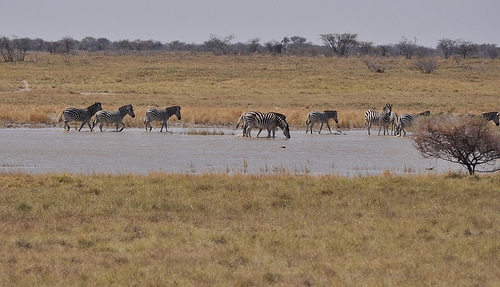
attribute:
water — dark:
[103, 137, 259, 169]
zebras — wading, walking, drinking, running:
[53, 93, 499, 141]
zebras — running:
[50, 97, 183, 134]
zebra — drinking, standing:
[238, 111, 292, 141]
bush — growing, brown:
[418, 116, 498, 182]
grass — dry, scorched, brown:
[158, 66, 223, 80]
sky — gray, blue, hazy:
[223, 3, 287, 27]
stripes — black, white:
[255, 118, 272, 126]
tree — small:
[421, 117, 471, 145]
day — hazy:
[161, 39, 248, 60]